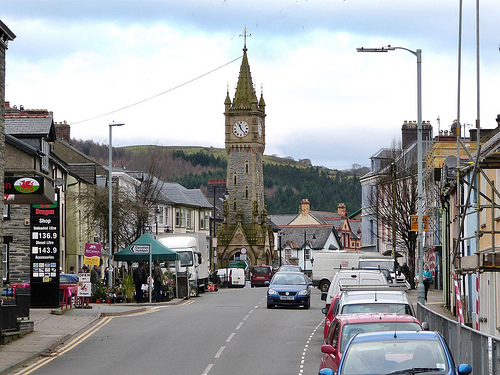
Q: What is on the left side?
A: The gas station.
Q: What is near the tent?
A: The white truck.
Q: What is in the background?
A: This is a tower.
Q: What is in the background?
A: The tan block clock tower.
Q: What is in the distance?
A: The clock tower.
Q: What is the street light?
A: Overhead.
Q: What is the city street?
A: Paved.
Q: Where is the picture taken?
A: A street.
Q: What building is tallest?
A: The clock tower.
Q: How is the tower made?
A: Of stone.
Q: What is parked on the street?
A: Cars.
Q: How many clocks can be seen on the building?
A: Two.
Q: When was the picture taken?
A: Daytime.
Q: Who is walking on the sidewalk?
A: Pedestrian.